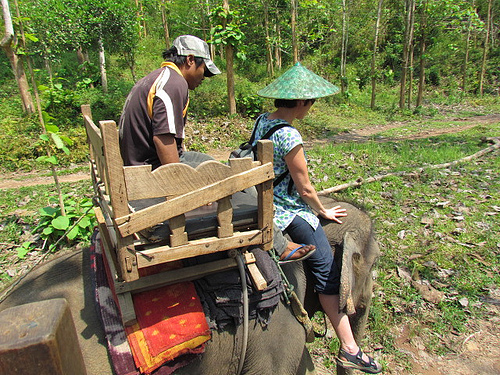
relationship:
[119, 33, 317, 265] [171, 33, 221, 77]
man wears baseball cap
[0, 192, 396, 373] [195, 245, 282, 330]
elephant has blanket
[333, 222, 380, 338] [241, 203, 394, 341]
head of an elephant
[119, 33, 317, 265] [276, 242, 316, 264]
man wearing sandal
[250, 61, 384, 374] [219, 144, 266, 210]
person wearing backpack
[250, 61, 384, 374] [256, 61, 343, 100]
person wearing hat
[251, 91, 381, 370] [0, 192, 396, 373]
person riding an elephant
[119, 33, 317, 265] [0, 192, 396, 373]
man riding an elephant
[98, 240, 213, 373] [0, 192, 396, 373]
blanket on elephant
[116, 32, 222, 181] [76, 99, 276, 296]
man sitting in seat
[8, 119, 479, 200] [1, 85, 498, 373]
path on grass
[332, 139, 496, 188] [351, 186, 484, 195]
log on ground